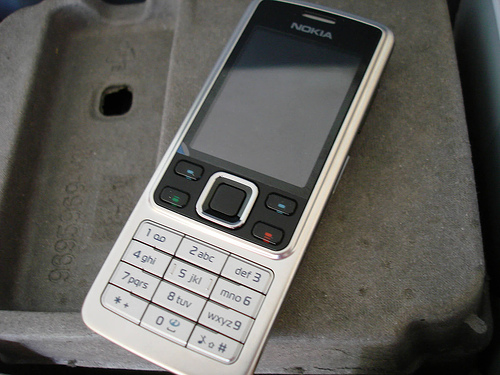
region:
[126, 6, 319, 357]
this is a phone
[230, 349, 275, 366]
the phone is white in color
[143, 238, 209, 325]
these are the buttons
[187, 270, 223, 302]
the buttons are white in color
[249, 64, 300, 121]
this is the screen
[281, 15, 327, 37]
this is a writing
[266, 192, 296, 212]
the button is black in color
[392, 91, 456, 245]
this is a sink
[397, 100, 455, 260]
the sink is made of stone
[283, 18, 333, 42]
the writing is in white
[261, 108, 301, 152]
part of a screen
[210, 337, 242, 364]
part of a button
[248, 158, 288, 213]
edge of a screem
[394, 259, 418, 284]
[part of a top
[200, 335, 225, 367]
part of a button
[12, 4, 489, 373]
Nokia cell phone sitting on top of a gray object.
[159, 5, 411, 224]
Screen of Nokia cell phone.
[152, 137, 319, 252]
Operation buttons of Nokia cell phone.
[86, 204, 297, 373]
Number pad of a Nokia cell phone.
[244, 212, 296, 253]
Power button of a Nokia cell phone.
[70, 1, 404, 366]
Silver and black cell phones.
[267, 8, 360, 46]
Logo lettering for Nokia, cell phone manufacturer.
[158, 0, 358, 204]
Screen of a cellphone that is turned off.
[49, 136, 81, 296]
Numbering on a gray object.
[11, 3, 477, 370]
Cell phone positioned in a 45 degree angle.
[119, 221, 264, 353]
keypad on a phone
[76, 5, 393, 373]
a grey and black cellular phone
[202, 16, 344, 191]
the display on a cell phone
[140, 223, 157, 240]
a number printed on a button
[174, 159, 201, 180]
a blue line on a button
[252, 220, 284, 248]
a red line on a button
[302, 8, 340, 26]
an ear speaker on a cell phone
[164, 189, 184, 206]
a green line on a button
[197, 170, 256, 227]
a button surrounded by a sliver outline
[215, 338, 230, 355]
a pound symbol on a button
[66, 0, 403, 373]
a Nokia cell phone turned off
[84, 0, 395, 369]
a black and silver Nokia cell phone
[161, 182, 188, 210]
green button on cell phone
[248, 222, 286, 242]
red hang up button on cell phone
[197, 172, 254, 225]
navigation button on cell phone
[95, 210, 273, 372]
number pad on Nokia cell phone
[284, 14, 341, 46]
Nokia logo on top of cell phone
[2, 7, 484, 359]
gray styrofoam contained for cell phone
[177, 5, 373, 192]
blank screen of nokia cell phone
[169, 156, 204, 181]
blue button on cell phone